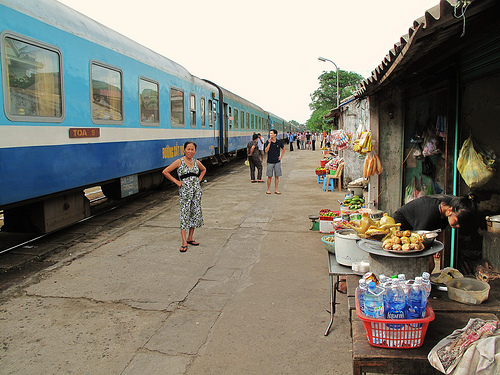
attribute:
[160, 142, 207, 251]
woman — posing, standing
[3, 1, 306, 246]
train — large, blue, white, two-tone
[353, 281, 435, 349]
basket — red, plastic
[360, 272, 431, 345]
water — bottled, tall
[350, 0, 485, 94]
roof — brown, tin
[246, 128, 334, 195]
people — waiting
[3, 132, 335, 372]
platform — concrete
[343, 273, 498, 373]
tables — wooden, brown, old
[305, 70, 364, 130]
tree — large, green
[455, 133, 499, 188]
bag — yellow, hanging, plastic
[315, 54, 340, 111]
light — modern, long, curved, silver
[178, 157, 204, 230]
dress — flowered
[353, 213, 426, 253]
food — yellow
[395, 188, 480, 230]
woman — bending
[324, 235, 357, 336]
table — silver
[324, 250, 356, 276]
edge — curved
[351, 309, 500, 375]
table — brown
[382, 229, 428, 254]
pastries — delicious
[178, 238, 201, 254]
flip flops — black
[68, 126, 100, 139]
sign — small, brown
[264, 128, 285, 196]
man — standing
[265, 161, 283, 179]
shorts — gray, grey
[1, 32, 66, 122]
window — large, clear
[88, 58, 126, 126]
window — large, clear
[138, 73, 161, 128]
window — large, clear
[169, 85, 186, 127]
window — large, clear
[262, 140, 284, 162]
shirt — black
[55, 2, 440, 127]
sky — grey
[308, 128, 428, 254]
food — for sale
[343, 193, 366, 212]
bananas — green